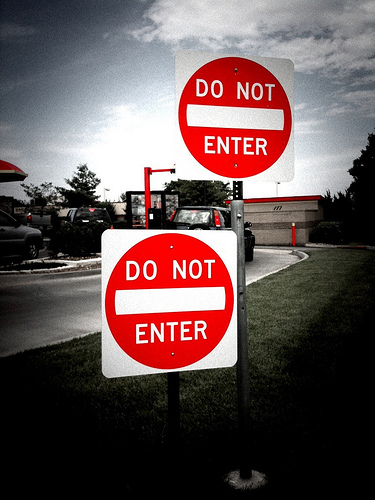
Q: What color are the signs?
A: Red and white.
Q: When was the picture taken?
A: Daytime.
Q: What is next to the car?
A: A menu.